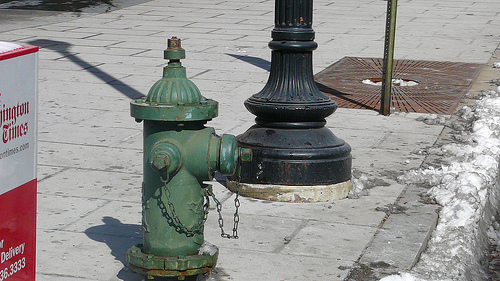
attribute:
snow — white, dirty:
[381, 58, 500, 281]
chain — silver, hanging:
[159, 162, 243, 241]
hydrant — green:
[129, 35, 256, 280]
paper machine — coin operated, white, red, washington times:
[1, 39, 36, 280]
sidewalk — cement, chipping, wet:
[1, 1, 500, 280]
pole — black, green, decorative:
[223, 1, 356, 204]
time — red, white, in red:
[2, 122, 32, 142]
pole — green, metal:
[379, 2, 397, 119]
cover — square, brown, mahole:
[304, 55, 486, 121]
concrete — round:
[225, 175, 353, 203]